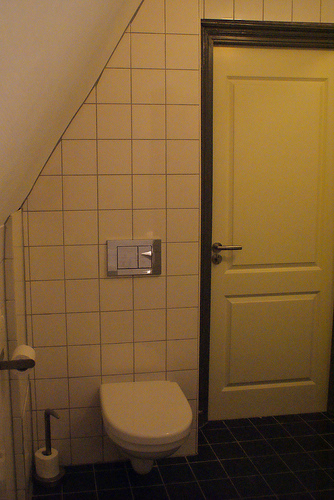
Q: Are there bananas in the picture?
A: No, there are no bananas.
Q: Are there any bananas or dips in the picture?
A: No, there are no bananas or dips.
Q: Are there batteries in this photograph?
A: No, there are no batteries.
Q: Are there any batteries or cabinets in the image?
A: No, there are no batteries or cabinets.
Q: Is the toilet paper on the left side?
A: Yes, the toilet paper is on the left of the image.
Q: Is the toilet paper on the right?
A: No, the toilet paper is on the left of the image.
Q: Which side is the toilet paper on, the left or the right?
A: The toilet paper is on the left of the image.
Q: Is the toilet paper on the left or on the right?
A: The toilet paper is on the left of the image.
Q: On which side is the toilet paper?
A: The toilet paper is on the left of the image.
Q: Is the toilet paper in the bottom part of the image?
A: Yes, the toilet paper is in the bottom of the image.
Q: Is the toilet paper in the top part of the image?
A: No, the toilet paper is in the bottom of the image.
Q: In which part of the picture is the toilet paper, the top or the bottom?
A: The toilet paper is in the bottom of the image.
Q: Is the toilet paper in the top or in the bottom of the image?
A: The toilet paper is in the bottom of the image.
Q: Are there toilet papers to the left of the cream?
A: Yes, there is a toilet paper to the left of the cream.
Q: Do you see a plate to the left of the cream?
A: No, there is a toilet paper to the left of the cream.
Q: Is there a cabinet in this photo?
A: No, there are no cabinets.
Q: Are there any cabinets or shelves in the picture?
A: No, there are no cabinets or shelves.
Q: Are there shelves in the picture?
A: No, there are no shelves.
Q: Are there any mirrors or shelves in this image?
A: No, there are no shelves or mirrors.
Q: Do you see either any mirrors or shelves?
A: No, there are no shelves or mirrors.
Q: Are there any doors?
A: Yes, there is a door.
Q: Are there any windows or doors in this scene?
A: Yes, there is a door.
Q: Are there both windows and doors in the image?
A: No, there is a door but no windows.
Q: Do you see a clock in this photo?
A: No, there are no clocks.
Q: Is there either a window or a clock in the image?
A: No, there are no clocks or windows.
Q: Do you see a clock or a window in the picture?
A: No, there are no clocks or windows.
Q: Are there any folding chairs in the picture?
A: No, there are no folding chairs.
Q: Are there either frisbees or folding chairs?
A: No, there are no folding chairs or frisbees.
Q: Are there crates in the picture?
A: No, there are no crates.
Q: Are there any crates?
A: No, there are no crates.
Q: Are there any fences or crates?
A: No, there are no crates or fences.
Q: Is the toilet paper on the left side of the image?
A: Yes, the toilet paper is on the left of the image.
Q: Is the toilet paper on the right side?
A: No, the toilet paper is on the left of the image.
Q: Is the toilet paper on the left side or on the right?
A: The toilet paper is on the left of the image.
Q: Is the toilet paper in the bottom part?
A: Yes, the toilet paper is in the bottom of the image.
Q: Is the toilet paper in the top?
A: No, the toilet paper is in the bottom of the image.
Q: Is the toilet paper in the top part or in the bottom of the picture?
A: The toilet paper is in the bottom of the image.